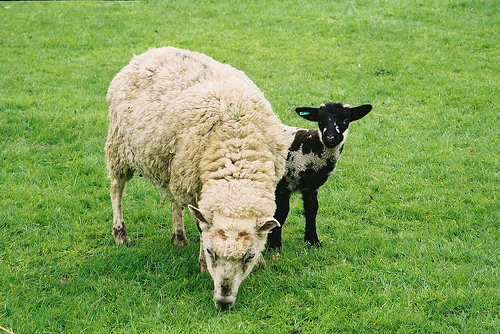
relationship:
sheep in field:
[97, 42, 289, 316] [9, 5, 491, 331]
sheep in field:
[263, 103, 373, 254] [9, 5, 491, 331]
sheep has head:
[97, 42, 289, 316] [189, 201, 279, 312]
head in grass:
[189, 201, 279, 312] [7, 4, 494, 329]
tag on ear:
[297, 108, 314, 118] [293, 103, 323, 121]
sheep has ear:
[263, 103, 373, 254] [293, 103, 323, 121]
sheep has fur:
[97, 42, 289, 316] [199, 105, 270, 172]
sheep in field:
[263, 98, 373, 253] [9, 5, 491, 331]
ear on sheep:
[183, 201, 215, 227] [97, 42, 289, 316]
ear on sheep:
[255, 213, 281, 235] [97, 42, 289, 316]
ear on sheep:
[294, 102, 323, 124] [263, 103, 373, 254]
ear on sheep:
[346, 103, 373, 120] [263, 103, 373, 254]